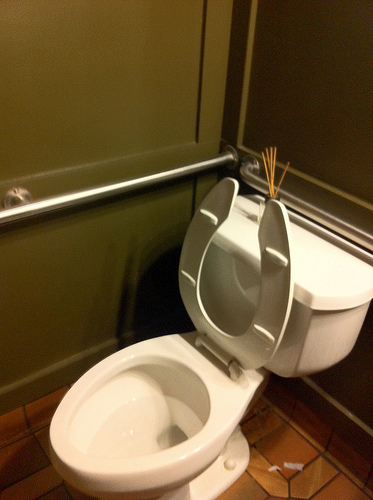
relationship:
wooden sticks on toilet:
[246, 146, 299, 207] [47, 238, 313, 493]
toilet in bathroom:
[57, 170, 363, 497] [3, 4, 365, 497]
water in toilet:
[90, 390, 198, 460] [57, 170, 363, 497]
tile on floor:
[260, 434, 353, 496] [9, 357, 368, 500]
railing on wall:
[0, 144, 237, 229] [211, 0, 371, 481]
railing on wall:
[236, 152, 371, 256] [0, 0, 233, 411]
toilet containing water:
[46, 178, 373, 499] [83, 392, 204, 459]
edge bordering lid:
[240, 198, 295, 369] [173, 176, 295, 372]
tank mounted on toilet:
[298, 239, 349, 303] [45, 199, 352, 496]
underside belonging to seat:
[177, 177, 290, 372] [181, 182, 289, 366]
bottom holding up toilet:
[144, 428, 251, 495] [57, 170, 363, 497]